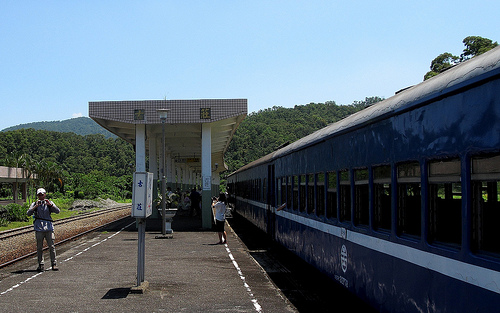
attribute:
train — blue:
[221, 38, 499, 311]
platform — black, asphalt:
[7, 182, 346, 302]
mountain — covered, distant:
[4, 112, 125, 192]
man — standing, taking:
[23, 183, 66, 272]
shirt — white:
[210, 199, 227, 220]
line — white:
[220, 237, 265, 312]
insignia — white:
[331, 238, 355, 285]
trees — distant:
[76, 154, 110, 195]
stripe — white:
[224, 186, 500, 293]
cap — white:
[33, 186, 51, 195]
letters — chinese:
[134, 178, 145, 213]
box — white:
[130, 169, 156, 219]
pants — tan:
[34, 224, 63, 264]